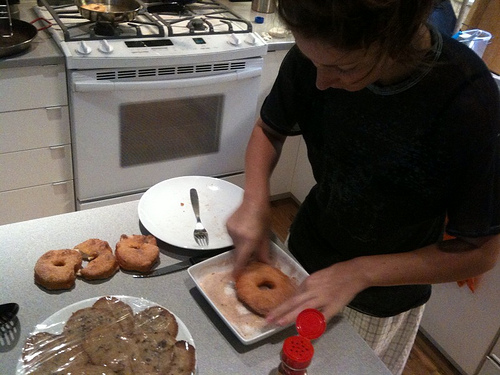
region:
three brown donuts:
[28, 227, 174, 288]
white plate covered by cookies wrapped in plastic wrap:
[17, 295, 199, 374]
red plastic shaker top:
[275, 304, 330, 371]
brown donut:
[232, 257, 307, 319]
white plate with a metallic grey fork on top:
[135, 163, 261, 257]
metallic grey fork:
[185, 184, 211, 250]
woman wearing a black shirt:
[217, 0, 498, 374]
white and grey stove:
[30, 2, 275, 214]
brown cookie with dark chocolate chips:
[127, 331, 174, 373]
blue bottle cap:
[252, 11, 264, 27]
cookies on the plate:
[26, 303, 212, 373]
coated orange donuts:
[35, 233, 165, 281]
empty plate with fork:
[133, 166, 236, 253]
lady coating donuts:
[200, 1, 470, 338]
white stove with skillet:
[44, 0, 257, 222]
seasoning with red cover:
[266, 309, 318, 371]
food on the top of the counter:
[8, 226, 338, 373]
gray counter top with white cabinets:
[8, 50, 78, 230]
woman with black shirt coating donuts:
[258, 23, 473, 373]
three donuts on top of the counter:
[25, 235, 142, 270]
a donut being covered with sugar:
[231, 257, 290, 312]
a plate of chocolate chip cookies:
[20, 297, 206, 374]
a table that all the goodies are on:
[0, 195, 400, 373]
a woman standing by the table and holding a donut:
[230, 0, 497, 370]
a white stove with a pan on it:
[45, 5, 269, 200]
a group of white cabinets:
[1, 64, 75, 218]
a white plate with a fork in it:
[133, 172, 247, 257]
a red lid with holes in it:
[277, 305, 321, 374]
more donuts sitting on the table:
[37, 240, 163, 285]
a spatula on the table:
[3, 300, 15, 327]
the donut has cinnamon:
[249, 256, 297, 310]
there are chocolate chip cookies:
[45, 314, 155, 374]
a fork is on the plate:
[178, 190, 215, 256]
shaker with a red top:
[282, 311, 320, 371]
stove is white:
[81, 26, 264, 187]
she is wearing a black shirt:
[275, 84, 448, 272]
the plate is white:
[150, 211, 184, 243]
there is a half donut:
[78, 234, 113, 281]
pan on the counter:
[0, 21, 35, 51]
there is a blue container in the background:
[446, 19, 482, 61]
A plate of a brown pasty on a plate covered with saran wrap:
[10, 292, 201, 372]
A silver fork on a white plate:
[135, 170, 245, 250]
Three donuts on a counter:
[36, 229, 168, 288]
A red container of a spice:
[276, 308, 330, 374]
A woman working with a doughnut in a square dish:
[190, 0, 498, 346]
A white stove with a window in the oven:
[57, 28, 271, 210]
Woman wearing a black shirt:
[260, 26, 498, 315]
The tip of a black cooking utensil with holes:
[0, 295, 18, 335]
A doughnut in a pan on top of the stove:
[76, 0, 153, 40]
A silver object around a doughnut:
[117, 232, 191, 287]